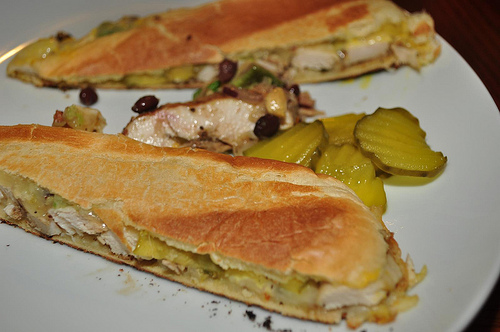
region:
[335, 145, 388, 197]
a pickle on a plate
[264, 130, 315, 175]
a pickle on plate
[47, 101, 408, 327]
a sandwich on plate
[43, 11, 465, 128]
a sandwich on a plet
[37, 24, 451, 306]
a sandiwch cut in half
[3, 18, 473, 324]
Sandwich is placed on the plate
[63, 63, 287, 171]
Capers are placed between the pieces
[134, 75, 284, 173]
Piece of chicken is on the plate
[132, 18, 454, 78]
Chicken and cheese are prominent on the plate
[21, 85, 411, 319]
Bread crust is used for the sandwich top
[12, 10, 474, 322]
artisan sandwich is placed on the white plate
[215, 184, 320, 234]
brown toast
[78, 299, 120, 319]
the plate is white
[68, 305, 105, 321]
a white plate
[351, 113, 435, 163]
pickles on the plate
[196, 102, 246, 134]
meat on the plate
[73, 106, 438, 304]
food on the plate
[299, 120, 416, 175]
the pickles are green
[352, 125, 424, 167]
green pickles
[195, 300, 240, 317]
spices on the plate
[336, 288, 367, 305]
meat on the sandwhich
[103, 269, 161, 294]
crumbs on the plate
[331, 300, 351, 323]
small hole in the sandwich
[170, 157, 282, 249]
grill lines on the sandwich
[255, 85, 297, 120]
small white bean on plate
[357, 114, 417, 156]
lines in the green pickle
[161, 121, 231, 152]
juice running out of the meat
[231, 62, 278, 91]
green herb on plate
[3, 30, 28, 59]
shine at edge of white plate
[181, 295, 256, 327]
tiny crumbs along side sandwich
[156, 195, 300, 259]
lines on top of the roll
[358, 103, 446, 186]
sliced green pickle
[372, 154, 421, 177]
edge of green pickle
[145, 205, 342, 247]
burnt color on roll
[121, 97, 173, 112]
small brown raisin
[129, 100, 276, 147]
juicy piece of pork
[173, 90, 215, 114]
crust on the pork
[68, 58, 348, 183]
Chicken in between the two pieces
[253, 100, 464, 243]
Pickles next to the sandwich on the plate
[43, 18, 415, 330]
Cheese and chicken on the sandwich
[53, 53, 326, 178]
Capers are sprinkled on the plate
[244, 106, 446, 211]
the pickles are slice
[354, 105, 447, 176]
the pickle slice is green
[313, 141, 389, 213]
the pickle slice is green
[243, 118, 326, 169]
the pickle slice is green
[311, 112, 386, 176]
the pickle slice is green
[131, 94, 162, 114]
the bean is black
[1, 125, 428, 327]
the sandwich is cut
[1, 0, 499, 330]
the plate is white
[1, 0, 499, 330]
the food on the plate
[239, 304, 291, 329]
the crumbs are black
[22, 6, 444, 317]
Food on white plate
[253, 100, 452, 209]
Pickles on the plate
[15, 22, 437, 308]
Sandwiches on the plate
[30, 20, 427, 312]
Food on the plate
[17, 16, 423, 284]
Food on round plate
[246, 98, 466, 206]
Pickle slices on the plate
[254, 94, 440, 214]
Pickle slices on white plate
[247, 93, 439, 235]
Pickle slices between sandwich halves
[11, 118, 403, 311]
Food in a piece of bread